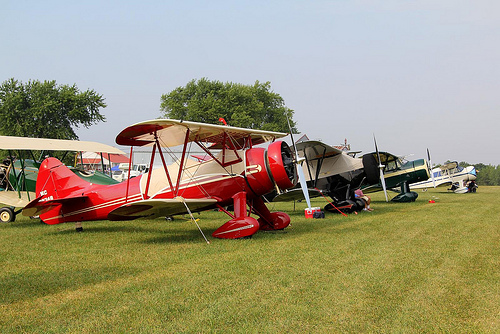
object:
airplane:
[0, 135, 129, 223]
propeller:
[373, 132, 389, 203]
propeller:
[279, 101, 311, 209]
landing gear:
[211, 192, 290, 239]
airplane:
[344, 147, 436, 203]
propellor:
[426, 148, 435, 189]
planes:
[261, 132, 389, 215]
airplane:
[388, 160, 480, 194]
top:
[42, 79, 58, 87]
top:
[197, 77, 213, 87]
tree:
[0, 77, 108, 165]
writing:
[40, 191, 45, 197]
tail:
[23, 156, 105, 225]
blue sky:
[265, 30, 350, 78]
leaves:
[208, 89, 215, 94]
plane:
[22, 105, 312, 240]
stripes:
[160, 175, 239, 194]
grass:
[0, 185, 500, 334]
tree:
[159, 76, 301, 144]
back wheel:
[0, 207, 16, 223]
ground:
[0, 172, 500, 334]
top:
[253, 80, 272, 94]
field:
[0, 185, 500, 334]